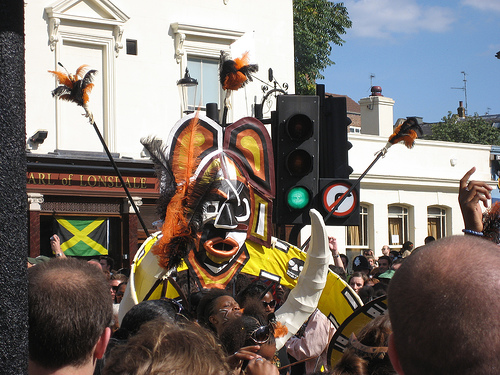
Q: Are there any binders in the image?
A: No, there are no binders.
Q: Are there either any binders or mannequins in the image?
A: No, there are no binders or mannequins.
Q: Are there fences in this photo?
A: No, there are no fences.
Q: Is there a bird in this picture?
A: No, there are no birds.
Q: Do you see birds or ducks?
A: No, there are no birds or ducks.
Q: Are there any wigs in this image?
A: No, there are no wigs.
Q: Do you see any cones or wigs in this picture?
A: No, there are no wigs or cones.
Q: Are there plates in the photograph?
A: No, there are no plates.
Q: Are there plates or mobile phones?
A: No, there are no plates or mobile phones.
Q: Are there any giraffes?
A: No, there are no giraffes.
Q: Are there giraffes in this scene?
A: No, there are no giraffes.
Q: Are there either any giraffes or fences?
A: No, there are no giraffes or fences.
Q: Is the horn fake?
A: Yes, the horn is fake.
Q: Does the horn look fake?
A: Yes, the horn is fake.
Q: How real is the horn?
A: The horn is fake.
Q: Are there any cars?
A: No, there are no cars.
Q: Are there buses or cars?
A: No, there are no cars or buses.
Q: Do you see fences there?
A: No, there are no fences.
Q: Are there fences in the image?
A: No, there are no fences.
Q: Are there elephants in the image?
A: No, there are no elephants.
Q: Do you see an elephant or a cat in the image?
A: No, there are no elephants or cats.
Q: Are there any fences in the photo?
A: No, there are no fences.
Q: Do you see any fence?
A: No, there are no fences.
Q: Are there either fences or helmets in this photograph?
A: No, there are no fences or helmets.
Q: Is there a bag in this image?
A: No, there are no bags.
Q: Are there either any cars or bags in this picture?
A: No, there are no bags or cars.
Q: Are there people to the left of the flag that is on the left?
A: No, the person is to the right of the flag.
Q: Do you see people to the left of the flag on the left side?
A: No, the person is to the right of the flag.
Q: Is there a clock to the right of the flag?
A: No, there is a person to the right of the flag.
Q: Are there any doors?
A: Yes, there is a door.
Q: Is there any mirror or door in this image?
A: Yes, there is a door.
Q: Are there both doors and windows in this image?
A: Yes, there are both a door and a window.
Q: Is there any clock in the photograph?
A: No, there are no clocks.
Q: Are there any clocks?
A: No, there are no clocks.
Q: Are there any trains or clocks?
A: No, there are no clocks or trains.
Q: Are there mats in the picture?
A: No, there are no mats.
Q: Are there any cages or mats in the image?
A: No, there are no mats or cages.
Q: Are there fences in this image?
A: No, there are no fences.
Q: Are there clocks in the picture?
A: No, there are no clocks.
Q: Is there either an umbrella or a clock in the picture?
A: No, there are no clocks or umbrellas.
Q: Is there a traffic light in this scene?
A: Yes, there is a traffic light.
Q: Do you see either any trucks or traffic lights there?
A: Yes, there is a traffic light.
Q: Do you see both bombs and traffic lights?
A: No, there is a traffic light but no bombs.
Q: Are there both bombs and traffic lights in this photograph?
A: No, there is a traffic light but no bombs.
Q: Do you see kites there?
A: No, there are no kites.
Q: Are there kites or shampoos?
A: No, there are no kites or shampoos.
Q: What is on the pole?
A: The traffic signal is on the pole.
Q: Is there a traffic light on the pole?
A: Yes, there is a traffic light on the pole.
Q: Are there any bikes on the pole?
A: No, there is a traffic light on the pole.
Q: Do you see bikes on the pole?
A: No, there is a traffic light on the pole.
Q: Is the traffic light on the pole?
A: Yes, the traffic light is on the pole.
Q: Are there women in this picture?
A: Yes, there is a woman.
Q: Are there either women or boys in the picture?
A: Yes, there is a woman.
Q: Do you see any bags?
A: No, there are no bags.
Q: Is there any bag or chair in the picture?
A: No, there are no bags or chairs.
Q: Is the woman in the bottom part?
A: Yes, the woman is in the bottom of the image.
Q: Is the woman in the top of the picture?
A: No, the woman is in the bottom of the image.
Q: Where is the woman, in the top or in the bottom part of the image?
A: The woman is in the bottom of the image.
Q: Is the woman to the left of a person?
A: Yes, the woman is to the left of a person.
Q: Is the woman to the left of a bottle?
A: No, the woman is to the left of a person.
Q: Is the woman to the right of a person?
A: No, the woman is to the left of a person.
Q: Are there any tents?
A: No, there are no tents.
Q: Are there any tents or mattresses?
A: No, there are no tents or mattresses.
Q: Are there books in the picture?
A: No, there are no books.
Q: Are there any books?
A: No, there are no books.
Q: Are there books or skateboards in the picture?
A: No, there are no books or skateboards.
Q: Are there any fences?
A: No, there are no fences.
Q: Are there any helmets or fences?
A: No, there are no fences or helmets.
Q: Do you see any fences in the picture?
A: No, there are no fences.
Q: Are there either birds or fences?
A: No, there are no fences or birds.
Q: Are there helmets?
A: No, there are no helmets.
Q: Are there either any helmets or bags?
A: No, there are no helmets or bags.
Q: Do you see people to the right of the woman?
A: Yes, there is a person to the right of the woman.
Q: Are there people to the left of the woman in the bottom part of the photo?
A: No, the person is to the right of the woman.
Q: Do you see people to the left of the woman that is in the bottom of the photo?
A: No, the person is to the right of the woman.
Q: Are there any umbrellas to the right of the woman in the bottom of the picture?
A: No, there is a person to the right of the woman.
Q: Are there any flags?
A: Yes, there is a flag.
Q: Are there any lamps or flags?
A: Yes, there is a flag.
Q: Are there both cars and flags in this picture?
A: No, there is a flag but no cars.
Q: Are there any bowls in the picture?
A: No, there are no bowls.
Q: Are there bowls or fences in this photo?
A: No, there are no bowls or fences.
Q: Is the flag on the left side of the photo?
A: Yes, the flag is on the left of the image.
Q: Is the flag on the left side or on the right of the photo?
A: The flag is on the left of the image.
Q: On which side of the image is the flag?
A: The flag is on the left of the image.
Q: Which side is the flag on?
A: The flag is on the left of the image.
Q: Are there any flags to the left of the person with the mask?
A: Yes, there is a flag to the left of the person.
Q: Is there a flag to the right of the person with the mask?
A: No, the flag is to the left of the person.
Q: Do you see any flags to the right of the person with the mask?
A: No, the flag is to the left of the person.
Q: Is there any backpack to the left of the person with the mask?
A: No, there is a flag to the left of the person.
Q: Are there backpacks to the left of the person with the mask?
A: No, there is a flag to the left of the person.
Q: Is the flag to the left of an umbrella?
A: No, the flag is to the left of a person.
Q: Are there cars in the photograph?
A: No, there are no cars.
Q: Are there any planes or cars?
A: No, there are no cars or planes.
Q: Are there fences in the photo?
A: No, there are no fences.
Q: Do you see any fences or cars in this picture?
A: No, there are no fences or cars.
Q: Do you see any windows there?
A: Yes, there is a window.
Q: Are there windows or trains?
A: Yes, there is a window.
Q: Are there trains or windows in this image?
A: Yes, there is a window.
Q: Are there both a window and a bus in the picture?
A: No, there is a window but no buses.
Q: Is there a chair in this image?
A: No, there are no chairs.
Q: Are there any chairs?
A: No, there are no chairs.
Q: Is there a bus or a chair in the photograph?
A: No, there are no chairs or buses.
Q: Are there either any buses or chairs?
A: No, there are no chairs or buses.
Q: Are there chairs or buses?
A: No, there are no chairs or buses.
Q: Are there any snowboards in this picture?
A: No, there are no snowboards.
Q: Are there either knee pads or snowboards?
A: No, there are no snowboards or knee pads.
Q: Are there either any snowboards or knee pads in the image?
A: No, there are no snowboards or knee pads.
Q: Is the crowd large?
A: Yes, the crowd is large.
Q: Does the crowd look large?
A: Yes, the crowd is large.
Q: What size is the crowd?
A: The crowd is large.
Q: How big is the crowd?
A: The crowd is large.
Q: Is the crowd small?
A: No, the crowd is large.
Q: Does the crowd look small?
A: No, the crowd is large.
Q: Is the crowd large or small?
A: The crowd is large.